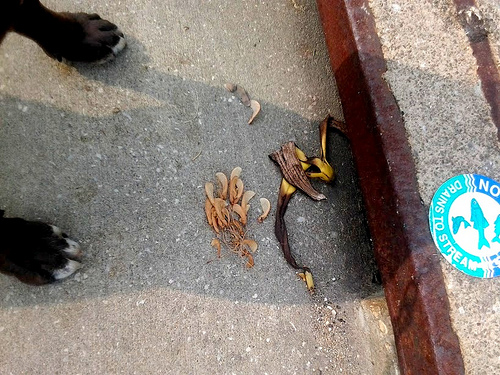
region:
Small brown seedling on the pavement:
[242, 98, 267, 129]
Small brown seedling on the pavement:
[258, 193, 271, 221]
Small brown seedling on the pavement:
[203, 181, 216, 200]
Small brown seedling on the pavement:
[215, 171, 229, 198]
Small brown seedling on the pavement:
[225, 164, 242, 194]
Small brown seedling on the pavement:
[186, 176, 267, 279]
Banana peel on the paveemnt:
[265, 127, 349, 294]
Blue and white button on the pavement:
[411, 143, 493, 311]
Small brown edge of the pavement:
[322, 5, 454, 374]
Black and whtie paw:
[44, 5, 144, 83]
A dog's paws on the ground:
[0, 0, 175, 310]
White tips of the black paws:
[46, 221, 88, 283]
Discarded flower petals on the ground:
[186, 158, 283, 278]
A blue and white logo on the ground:
[424, 171, 499, 280]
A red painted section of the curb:
[334, 0, 394, 267]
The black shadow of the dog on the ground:
[0, 36, 499, 336]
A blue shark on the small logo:
[463, 197, 496, 252]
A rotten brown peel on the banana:
[272, 136, 323, 198]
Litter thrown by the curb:
[197, 78, 390, 298]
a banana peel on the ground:
[268, 111, 367, 348]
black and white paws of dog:
[37, 13, 137, 318]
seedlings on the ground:
[184, 163, 283, 285]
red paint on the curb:
[324, 6, 456, 373]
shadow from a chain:
[371, 267, 458, 349]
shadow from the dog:
[13, 82, 499, 324]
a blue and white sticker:
[438, 157, 497, 286]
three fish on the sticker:
[447, 190, 499, 257]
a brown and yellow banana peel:
[256, 104, 341, 276]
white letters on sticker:
[434, 156, 499, 278]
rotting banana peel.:
[270, 105, 352, 301]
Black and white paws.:
[15, 7, 129, 287]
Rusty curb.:
[311, 2, 468, 374]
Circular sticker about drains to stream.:
[428, 169, 499, 278]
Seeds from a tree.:
[198, 169, 271, 271]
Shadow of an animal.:
[1, 54, 498, 310]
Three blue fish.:
[449, 195, 499, 250]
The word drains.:
[428, 173, 463, 216]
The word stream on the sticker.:
[435, 232, 481, 269]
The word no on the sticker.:
[473, 176, 498, 197]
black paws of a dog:
[2, 3, 129, 292]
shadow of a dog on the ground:
[5, 43, 498, 299]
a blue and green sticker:
[427, 170, 494, 279]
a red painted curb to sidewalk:
[324, 2, 467, 373]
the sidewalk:
[330, 3, 496, 372]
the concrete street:
[0, 3, 397, 372]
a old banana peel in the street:
[275, 116, 351, 294]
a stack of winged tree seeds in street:
[205, 78, 269, 265]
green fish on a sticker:
[450, 199, 499, 247]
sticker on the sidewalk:
[430, 171, 497, 279]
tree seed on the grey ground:
[257, 198, 273, 225]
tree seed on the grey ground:
[249, 97, 261, 123]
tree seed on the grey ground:
[242, 236, 256, 252]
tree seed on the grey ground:
[212, 170, 228, 200]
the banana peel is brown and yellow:
[268, 115, 348, 295]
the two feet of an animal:
[1, 0, 128, 284]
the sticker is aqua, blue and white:
[427, 174, 499, 276]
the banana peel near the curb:
[271, 0, 497, 373]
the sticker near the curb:
[315, 0, 496, 372]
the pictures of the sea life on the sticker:
[427, 173, 499, 279]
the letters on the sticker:
[428, 173, 499, 280]